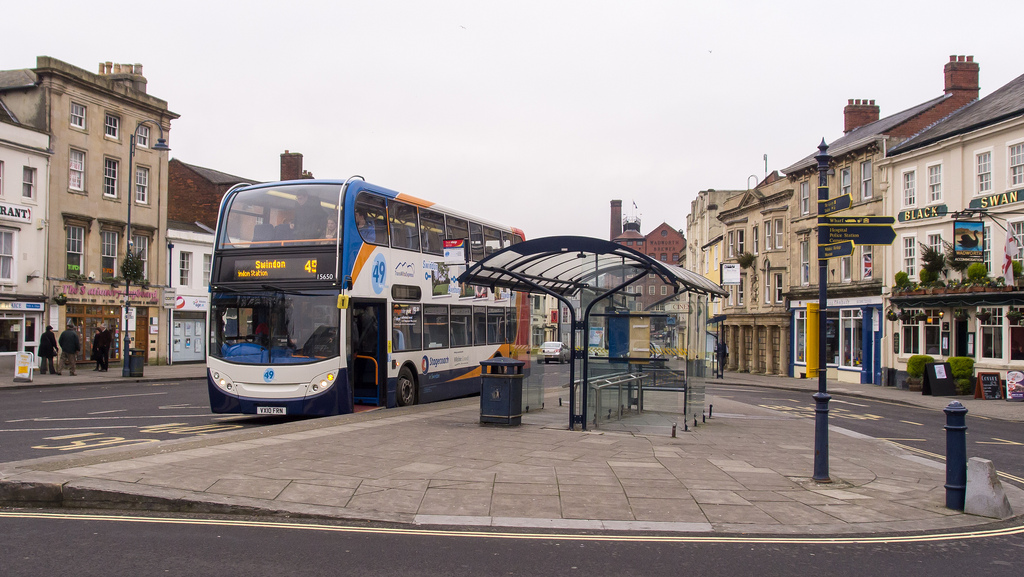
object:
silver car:
[536, 341, 573, 364]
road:
[528, 362, 624, 384]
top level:
[203, 179, 531, 251]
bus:
[206, 179, 544, 419]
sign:
[896, 208, 947, 221]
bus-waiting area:
[452, 230, 732, 445]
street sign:
[810, 182, 898, 262]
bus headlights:
[205, 368, 238, 392]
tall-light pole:
[115, 111, 143, 385]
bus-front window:
[213, 282, 341, 360]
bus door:
[339, 292, 396, 415]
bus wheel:
[393, 363, 418, 408]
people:
[56, 324, 84, 376]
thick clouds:
[465, 59, 575, 139]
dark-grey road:
[2, 379, 189, 436]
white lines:
[40, 389, 168, 404]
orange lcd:
[230, 257, 317, 279]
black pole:
[796, 135, 846, 484]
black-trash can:
[476, 350, 531, 426]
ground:
[101, 376, 966, 534]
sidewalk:
[688, 390, 890, 527]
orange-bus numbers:
[302, 259, 318, 275]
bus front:
[202, 175, 356, 420]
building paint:
[785, 292, 891, 385]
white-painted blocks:
[410, 512, 493, 527]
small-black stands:
[663, 421, 685, 441]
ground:
[622, 387, 759, 496]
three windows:
[65, 97, 154, 153]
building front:
[39, 55, 173, 369]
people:
[37, 323, 59, 374]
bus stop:
[453, 238, 732, 440]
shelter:
[456, 235, 730, 437]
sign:
[815, 240, 857, 261]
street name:
[829, 216, 874, 226]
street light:
[117, 115, 169, 375]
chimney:
[841, 98, 880, 133]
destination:
[251, 258, 288, 270]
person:
[95, 322, 111, 371]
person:
[93, 326, 109, 372]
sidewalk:
[2, 355, 219, 382]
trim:
[854, 303, 889, 387]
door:
[859, 314, 872, 382]